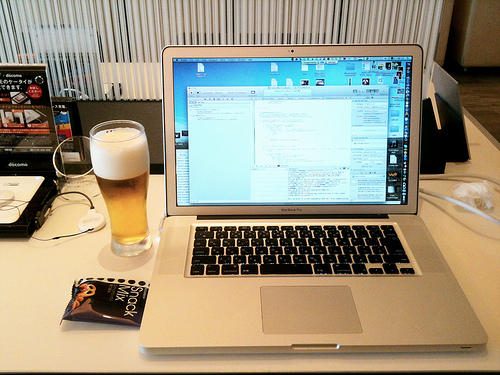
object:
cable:
[419, 173, 500, 227]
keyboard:
[190, 225, 416, 276]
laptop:
[138, 43, 489, 355]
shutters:
[0, 0, 443, 102]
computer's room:
[0, 0, 500, 375]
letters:
[281, 208, 303, 211]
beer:
[90, 120, 153, 258]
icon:
[271, 62, 278, 71]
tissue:
[451, 179, 494, 210]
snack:
[59, 277, 151, 326]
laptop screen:
[172, 55, 415, 208]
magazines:
[0, 64, 85, 181]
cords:
[26, 136, 95, 241]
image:
[72, 282, 97, 310]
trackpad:
[259, 284, 364, 334]